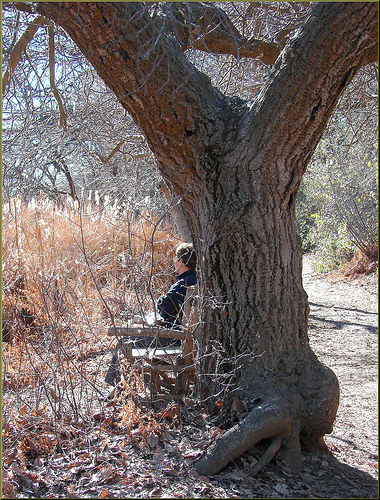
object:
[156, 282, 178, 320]
arm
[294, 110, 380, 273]
bush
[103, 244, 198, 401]
man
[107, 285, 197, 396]
bench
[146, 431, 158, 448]
leaf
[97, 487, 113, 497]
leaf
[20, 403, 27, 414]
leaf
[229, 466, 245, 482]
leaf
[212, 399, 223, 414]
leaf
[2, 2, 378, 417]
scene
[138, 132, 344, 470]
trunk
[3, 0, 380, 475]
tree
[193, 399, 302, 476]
roots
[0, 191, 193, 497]
brown brush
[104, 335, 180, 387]
gray pants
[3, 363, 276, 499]
brown leaves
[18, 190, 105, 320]
what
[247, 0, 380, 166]
limbs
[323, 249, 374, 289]
grass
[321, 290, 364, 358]
ground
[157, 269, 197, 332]
jacket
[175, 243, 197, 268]
hair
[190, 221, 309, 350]
tree trunk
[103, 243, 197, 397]
lady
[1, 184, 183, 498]
grass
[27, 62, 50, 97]
sky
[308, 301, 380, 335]
shadow